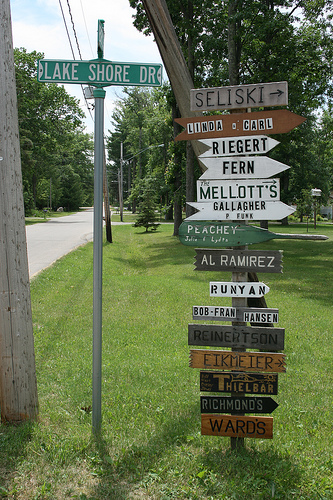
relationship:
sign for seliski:
[185, 77, 293, 116] [193, 86, 267, 108]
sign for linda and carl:
[171, 108, 308, 144] [186, 117, 274, 135]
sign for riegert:
[196, 133, 286, 159] [210, 136, 269, 156]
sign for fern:
[198, 153, 295, 184] [220, 159, 257, 175]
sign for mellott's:
[195, 176, 284, 204] [199, 184, 278, 199]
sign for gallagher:
[184, 199, 301, 226] [212, 201, 267, 214]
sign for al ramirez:
[191, 246, 289, 278] [200, 253, 277, 267]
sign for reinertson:
[184, 321, 288, 354] [193, 327, 279, 347]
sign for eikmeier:
[184, 346, 292, 377] [202, 351, 275, 371]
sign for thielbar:
[197, 369, 284, 396] [211, 373, 275, 395]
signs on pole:
[173, 80, 309, 441] [226, 103, 255, 458]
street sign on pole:
[33, 56, 165, 92] [90, 85, 106, 439]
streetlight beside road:
[116, 138, 167, 226] [21, 199, 114, 294]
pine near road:
[133, 185, 163, 236] [21, 199, 114, 294]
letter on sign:
[41, 60, 54, 83] [33, 56, 165, 92]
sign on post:
[33, 56, 165, 92] [90, 85, 106, 439]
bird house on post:
[310, 186, 324, 199] [311, 195, 319, 233]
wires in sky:
[56, 0, 118, 150] [10, 2, 331, 169]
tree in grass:
[133, 185, 163, 236] [2, 205, 331, 498]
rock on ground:
[55, 204, 65, 215] [23, 201, 83, 220]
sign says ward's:
[195, 409, 278, 445] [206, 415, 266, 436]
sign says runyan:
[208, 277, 272, 301] [210, 283, 265, 298]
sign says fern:
[198, 153, 295, 184] [220, 159, 257, 175]